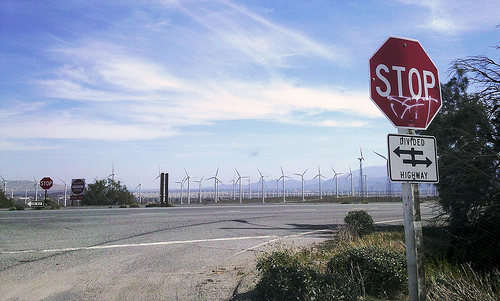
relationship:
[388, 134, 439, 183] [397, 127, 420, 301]
sign on pole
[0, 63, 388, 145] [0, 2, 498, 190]
cloud in sky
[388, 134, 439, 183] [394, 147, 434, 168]
sign has arrow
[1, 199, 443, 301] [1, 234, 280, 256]
street has line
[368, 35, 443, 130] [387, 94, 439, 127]
sign has graffiti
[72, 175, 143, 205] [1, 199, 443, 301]
bush next to street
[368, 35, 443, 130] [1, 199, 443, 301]
sign across street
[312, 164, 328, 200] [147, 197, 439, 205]
turbine in field